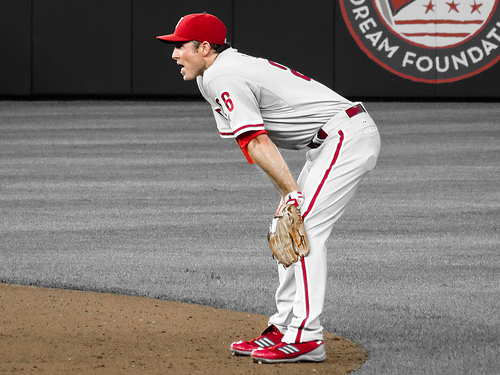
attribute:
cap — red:
[155, 11, 229, 48]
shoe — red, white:
[225, 323, 283, 354]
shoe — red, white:
[249, 336, 322, 366]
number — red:
[217, 89, 236, 113]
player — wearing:
[135, 60, 417, 360]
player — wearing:
[142, 60, 446, 366]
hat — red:
[211, 114, 245, 137]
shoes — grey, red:
[220, 309, 332, 375]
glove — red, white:
[255, 170, 319, 273]